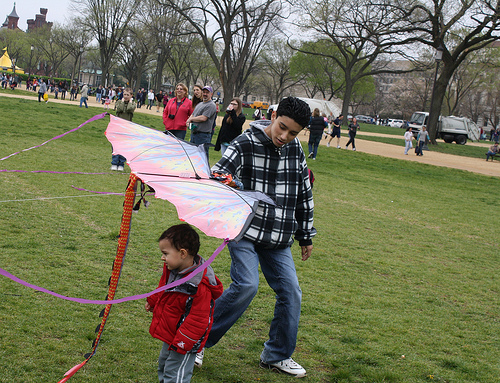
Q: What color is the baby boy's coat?
A: Red.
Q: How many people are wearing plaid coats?
A: 1.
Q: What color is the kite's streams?
A: Purple.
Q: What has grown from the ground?
A: Trees and grass.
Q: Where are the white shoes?
A: On the young man's feet.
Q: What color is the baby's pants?
A: Gray.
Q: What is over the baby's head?
A: A kite.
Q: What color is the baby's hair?
A: Black.